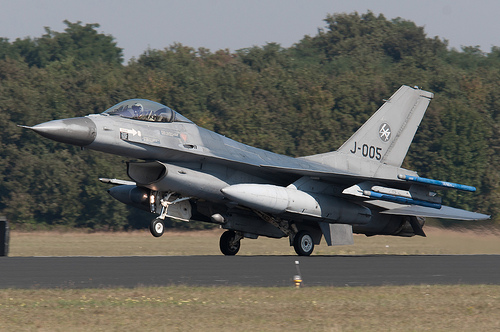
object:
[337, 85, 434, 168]
tail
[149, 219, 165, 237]
wheel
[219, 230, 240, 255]
wheel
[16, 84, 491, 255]
aircraft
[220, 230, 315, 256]
landing gear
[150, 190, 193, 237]
landing gear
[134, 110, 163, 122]
chair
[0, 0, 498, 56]
sky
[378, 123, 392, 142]
logo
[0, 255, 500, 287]
runway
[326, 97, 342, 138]
tree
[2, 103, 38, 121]
tree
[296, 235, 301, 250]
rubber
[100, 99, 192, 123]
window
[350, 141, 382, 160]
j-005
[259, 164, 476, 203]
wing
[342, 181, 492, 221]
wing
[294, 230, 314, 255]
tire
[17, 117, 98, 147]
nose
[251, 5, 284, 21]
clouds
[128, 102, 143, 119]
pilot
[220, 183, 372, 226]
missile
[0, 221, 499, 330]
airfield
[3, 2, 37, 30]
cloud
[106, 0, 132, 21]
cloud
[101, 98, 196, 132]
cockpit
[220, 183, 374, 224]
turbine